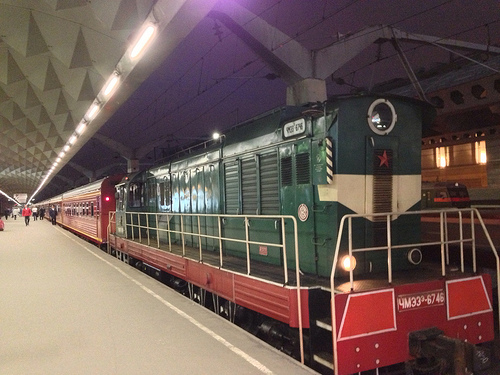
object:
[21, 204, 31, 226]
person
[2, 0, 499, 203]
roof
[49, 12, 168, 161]
overhang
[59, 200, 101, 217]
windows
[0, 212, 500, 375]
ground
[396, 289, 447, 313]
tag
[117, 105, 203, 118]
sky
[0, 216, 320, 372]
platform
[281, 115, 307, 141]
sign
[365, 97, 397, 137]
round window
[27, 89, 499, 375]
train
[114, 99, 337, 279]
side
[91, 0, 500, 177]
wires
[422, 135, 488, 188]
baseball player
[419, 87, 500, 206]
wall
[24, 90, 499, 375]
train car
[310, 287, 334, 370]
step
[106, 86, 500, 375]
engine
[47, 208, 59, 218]
dark coat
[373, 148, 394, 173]
star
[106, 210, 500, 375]
railing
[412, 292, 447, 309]
numbers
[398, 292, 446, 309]
letters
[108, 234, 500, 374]
bottom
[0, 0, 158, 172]
ceiling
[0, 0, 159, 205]
shapes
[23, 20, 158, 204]
lights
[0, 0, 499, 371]
building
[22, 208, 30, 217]
shirt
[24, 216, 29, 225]
pants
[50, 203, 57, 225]
person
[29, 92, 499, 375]
car